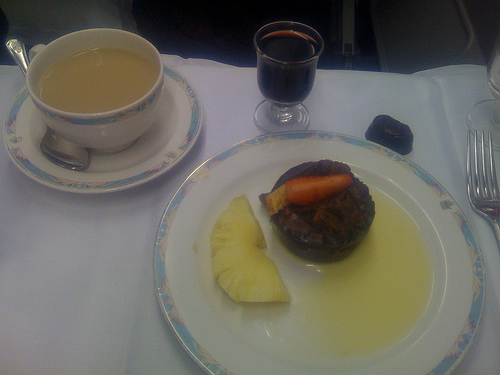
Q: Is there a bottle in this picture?
A: No, there are no bottles.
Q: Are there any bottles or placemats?
A: No, there are no bottles or placemats.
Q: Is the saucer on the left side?
A: Yes, the saucer is on the left of the image.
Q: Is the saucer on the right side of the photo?
A: No, the saucer is on the left of the image.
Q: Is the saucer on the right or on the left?
A: The saucer is on the left of the image.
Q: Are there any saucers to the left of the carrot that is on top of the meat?
A: Yes, there is a saucer to the left of the carrot.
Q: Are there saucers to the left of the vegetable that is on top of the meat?
A: Yes, there is a saucer to the left of the carrot.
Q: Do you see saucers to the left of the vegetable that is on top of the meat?
A: Yes, there is a saucer to the left of the carrot.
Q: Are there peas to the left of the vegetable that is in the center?
A: No, there is a saucer to the left of the carrot.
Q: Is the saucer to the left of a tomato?
A: No, the saucer is to the left of a carrot.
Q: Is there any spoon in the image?
A: Yes, there is a spoon.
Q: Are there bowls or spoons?
A: Yes, there is a spoon.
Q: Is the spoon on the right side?
A: No, the spoon is on the left of the image.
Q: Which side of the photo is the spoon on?
A: The spoon is on the left of the image.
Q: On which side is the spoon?
A: The spoon is on the left of the image.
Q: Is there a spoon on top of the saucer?
A: Yes, there is a spoon on top of the saucer.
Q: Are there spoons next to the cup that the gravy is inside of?
A: Yes, there is a spoon next to the cup.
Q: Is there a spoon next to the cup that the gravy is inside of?
A: Yes, there is a spoon next to the cup.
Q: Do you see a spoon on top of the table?
A: Yes, there is a spoon on top of the table.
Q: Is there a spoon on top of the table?
A: Yes, there is a spoon on top of the table.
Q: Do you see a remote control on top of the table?
A: No, there is a spoon on top of the table.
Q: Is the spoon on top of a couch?
A: No, the spoon is on top of a table.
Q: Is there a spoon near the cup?
A: Yes, there is a spoon near the cup.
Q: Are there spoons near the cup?
A: Yes, there is a spoon near the cup.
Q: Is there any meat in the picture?
A: Yes, there is meat.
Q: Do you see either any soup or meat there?
A: Yes, there is meat.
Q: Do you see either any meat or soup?
A: Yes, there is meat.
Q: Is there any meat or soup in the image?
A: Yes, there is meat.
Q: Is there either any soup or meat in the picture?
A: Yes, there is meat.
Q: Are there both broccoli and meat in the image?
A: No, there is meat but no broccoli.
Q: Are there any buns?
A: No, there are no buns.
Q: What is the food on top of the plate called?
A: The food is meat.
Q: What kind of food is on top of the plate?
A: The food is meat.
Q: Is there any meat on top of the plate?
A: Yes, there is meat on top of the plate.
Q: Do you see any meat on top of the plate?
A: Yes, there is meat on top of the plate.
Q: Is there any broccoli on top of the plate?
A: No, there is meat on top of the plate.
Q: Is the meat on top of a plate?
A: Yes, the meat is on top of a plate.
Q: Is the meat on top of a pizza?
A: No, the meat is on top of a plate.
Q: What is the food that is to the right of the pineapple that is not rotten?
A: The food is meat.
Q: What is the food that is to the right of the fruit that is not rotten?
A: The food is meat.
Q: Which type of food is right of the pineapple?
A: The food is meat.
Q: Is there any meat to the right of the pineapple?
A: Yes, there is meat to the right of the pineapple.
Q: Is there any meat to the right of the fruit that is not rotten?
A: Yes, there is meat to the right of the pineapple.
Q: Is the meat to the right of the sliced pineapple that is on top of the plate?
A: Yes, the meat is to the right of the pineapple.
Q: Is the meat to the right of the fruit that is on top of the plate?
A: Yes, the meat is to the right of the pineapple.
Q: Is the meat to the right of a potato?
A: No, the meat is to the right of the pineapple.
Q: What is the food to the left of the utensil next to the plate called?
A: The food is meat.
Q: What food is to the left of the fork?
A: The food is meat.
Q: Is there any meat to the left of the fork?
A: Yes, there is meat to the left of the fork.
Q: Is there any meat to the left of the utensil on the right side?
A: Yes, there is meat to the left of the fork.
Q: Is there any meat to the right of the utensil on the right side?
A: No, the meat is to the left of the fork.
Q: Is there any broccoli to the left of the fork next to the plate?
A: No, there is meat to the left of the fork.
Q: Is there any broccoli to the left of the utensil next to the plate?
A: No, there is meat to the left of the fork.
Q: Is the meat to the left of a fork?
A: Yes, the meat is to the left of a fork.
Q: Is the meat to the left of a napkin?
A: No, the meat is to the left of a fork.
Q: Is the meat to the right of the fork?
A: No, the meat is to the left of the fork.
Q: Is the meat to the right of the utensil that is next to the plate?
A: No, the meat is to the left of the fork.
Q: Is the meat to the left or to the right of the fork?
A: The meat is to the left of the fork.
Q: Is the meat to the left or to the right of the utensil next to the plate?
A: The meat is to the left of the fork.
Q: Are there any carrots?
A: Yes, there is a carrot.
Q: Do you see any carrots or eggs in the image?
A: Yes, there is a carrot.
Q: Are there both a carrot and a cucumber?
A: No, there is a carrot but no cucumbers.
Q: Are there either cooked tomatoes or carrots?
A: Yes, there is a cooked carrot.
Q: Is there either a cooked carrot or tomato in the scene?
A: Yes, there is a cooked carrot.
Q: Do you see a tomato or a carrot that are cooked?
A: Yes, the carrot is cooked.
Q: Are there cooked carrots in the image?
A: Yes, there is a cooked carrot.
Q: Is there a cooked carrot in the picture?
A: Yes, there is a cooked carrot.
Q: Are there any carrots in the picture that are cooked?
A: Yes, there is a carrot that is cooked.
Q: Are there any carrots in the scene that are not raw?
A: Yes, there is a cooked carrot.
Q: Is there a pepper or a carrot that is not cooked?
A: No, there is a carrot but it is cooked.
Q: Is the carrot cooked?
A: Yes, the carrot is cooked.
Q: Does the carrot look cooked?
A: Yes, the carrot is cooked.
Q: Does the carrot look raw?
A: No, the carrot is cooked.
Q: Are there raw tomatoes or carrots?
A: No, there is a carrot but it is cooked.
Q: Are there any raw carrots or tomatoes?
A: No, there is a carrot but it is cooked.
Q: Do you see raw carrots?
A: No, there is a carrot but it is cooked.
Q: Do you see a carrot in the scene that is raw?
A: No, there is a carrot but it is cooked.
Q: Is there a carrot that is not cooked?
A: No, there is a carrot but it is cooked.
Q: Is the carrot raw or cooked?
A: The carrot is cooked.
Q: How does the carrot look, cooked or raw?
A: The carrot is cooked.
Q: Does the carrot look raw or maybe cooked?
A: The carrot is cooked.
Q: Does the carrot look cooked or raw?
A: The carrot is cooked.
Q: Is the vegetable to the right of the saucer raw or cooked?
A: The carrot is cooked.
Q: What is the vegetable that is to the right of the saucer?
A: The vegetable is a carrot.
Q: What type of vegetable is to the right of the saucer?
A: The vegetable is a carrot.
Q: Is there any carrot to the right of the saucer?
A: Yes, there is a carrot to the right of the saucer.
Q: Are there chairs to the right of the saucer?
A: No, there is a carrot to the right of the saucer.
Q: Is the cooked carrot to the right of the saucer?
A: Yes, the carrot is to the right of the saucer.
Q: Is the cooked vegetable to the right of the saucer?
A: Yes, the carrot is to the right of the saucer.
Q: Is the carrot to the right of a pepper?
A: No, the carrot is to the right of the saucer.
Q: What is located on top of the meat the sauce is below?
A: The carrot is on top of the meat.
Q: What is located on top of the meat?
A: The carrot is on top of the meat.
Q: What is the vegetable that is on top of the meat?
A: The vegetable is a carrot.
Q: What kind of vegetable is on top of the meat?
A: The vegetable is a carrot.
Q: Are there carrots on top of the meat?
A: Yes, there is a carrot on top of the meat.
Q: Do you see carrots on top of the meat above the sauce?
A: Yes, there is a carrot on top of the meat.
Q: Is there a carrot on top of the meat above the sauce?
A: Yes, there is a carrot on top of the meat.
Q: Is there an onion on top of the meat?
A: No, there is a carrot on top of the meat.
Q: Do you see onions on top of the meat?
A: No, there is a carrot on top of the meat.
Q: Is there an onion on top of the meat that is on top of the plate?
A: No, there is a carrot on top of the meat.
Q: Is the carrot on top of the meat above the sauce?
A: Yes, the carrot is on top of the meat.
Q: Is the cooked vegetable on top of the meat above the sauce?
A: Yes, the carrot is on top of the meat.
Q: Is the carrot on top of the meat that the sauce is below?
A: Yes, the carrot is on top of the meat.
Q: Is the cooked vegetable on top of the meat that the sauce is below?
A: Yes, the carrot is on top of the meat.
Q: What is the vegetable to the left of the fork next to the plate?
A: The vegetable is a carrot.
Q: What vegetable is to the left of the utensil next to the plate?
A: The vegetable is a carrot.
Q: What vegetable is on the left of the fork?
A: The vegetable is a carrot.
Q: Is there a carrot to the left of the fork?
A: Yes, there is a carrot to the left of the fork.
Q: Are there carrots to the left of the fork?
A: Yes, there is a carrot to the left of the fork.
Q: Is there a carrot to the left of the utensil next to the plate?
A: Yes, there is a carrot to the left of the fork.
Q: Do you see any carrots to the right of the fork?
A: No, the carrot is to the left of the fork.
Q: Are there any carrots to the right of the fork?
A: No, the carrot is to the left of the fork.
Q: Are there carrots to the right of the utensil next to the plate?
A: No, the carrot is to the left of the fork.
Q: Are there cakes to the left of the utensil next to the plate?
A: No, there is a carrot to the left of the fork.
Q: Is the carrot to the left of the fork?
A: Yes, the carrot is to the left of the fork.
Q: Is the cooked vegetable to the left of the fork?
A: Yes, the carrot is to the left of the fork.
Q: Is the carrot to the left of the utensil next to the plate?
A: Yes, the carrot is to the left of the fork.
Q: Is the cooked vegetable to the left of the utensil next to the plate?
A: Yes, the carrot is to the left of the fork.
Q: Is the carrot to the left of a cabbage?
A: No, the carrot is to the left of the fork.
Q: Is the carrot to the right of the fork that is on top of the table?
A: No, the carrot is to the left of the fork.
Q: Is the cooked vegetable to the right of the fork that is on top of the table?
A: No, the carrot is to the left of the fork.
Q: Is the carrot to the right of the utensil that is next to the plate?
A: No, the carrot is to the left of the fork.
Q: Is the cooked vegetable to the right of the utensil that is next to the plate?
A: No, the carrot is to the left of the fork.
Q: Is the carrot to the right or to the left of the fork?
A: The carrot is to the left of the fork.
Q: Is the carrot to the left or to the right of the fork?
A: The carrot is to the left of the fork.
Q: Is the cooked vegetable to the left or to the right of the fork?
A: The carrot is to the left of the fork.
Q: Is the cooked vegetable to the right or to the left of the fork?
A: The carrot is to the left of the fork.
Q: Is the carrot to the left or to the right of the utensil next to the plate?
A: The carrot is to the left of the fork.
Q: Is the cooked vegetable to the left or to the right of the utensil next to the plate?
A: The carrot is to the left of the fork.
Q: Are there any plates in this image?
A: Yes, there is a plate.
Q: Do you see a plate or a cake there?
A: Yes, there is a plate.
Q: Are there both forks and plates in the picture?
A: Yes, there are both a plate and a fork.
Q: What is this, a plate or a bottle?
A: This is a plate.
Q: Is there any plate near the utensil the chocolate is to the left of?
A: Yes, there is a plate near the fork.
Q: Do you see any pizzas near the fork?
A: No, there is a plate near the fork.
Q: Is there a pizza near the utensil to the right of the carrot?
A: No, there is a plate near the fork.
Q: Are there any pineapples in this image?
A: Yes, there is a pineapple.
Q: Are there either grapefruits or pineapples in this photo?
A: Yes, there is a pineapple.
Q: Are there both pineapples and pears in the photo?
A: No, there is a pineapple but no pears.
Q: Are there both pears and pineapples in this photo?
A: No, there is a pineapple but no pears.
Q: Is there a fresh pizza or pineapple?
A: Yes, there is a fresh pineapple.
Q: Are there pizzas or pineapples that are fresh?
A: Yes, the pineapple is fresh.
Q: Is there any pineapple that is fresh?
A: Yes, there is a fresh pineapple.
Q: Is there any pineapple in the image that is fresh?
A: Yes, there is a pineapple that is fresh.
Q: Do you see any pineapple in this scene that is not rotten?
A: Yes, there is a fresh pineapple.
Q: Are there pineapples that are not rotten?
A: Yes, there is a fresh pineapple.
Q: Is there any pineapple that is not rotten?
A: Yes, there is a fresh pineapple.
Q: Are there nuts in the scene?
A: No, there are no nuts.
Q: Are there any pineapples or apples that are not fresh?
A: No, there is a pineapple but it is fresh.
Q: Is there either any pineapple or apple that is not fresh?
A: No, there is a pineapple but it is fresh.